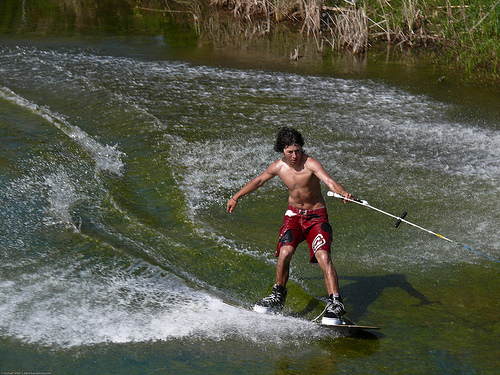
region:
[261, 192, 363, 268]
Man wearing red shorts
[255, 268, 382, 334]
man on a water board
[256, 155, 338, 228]
man without a shirt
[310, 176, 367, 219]
man holding a line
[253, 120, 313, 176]
man with black hair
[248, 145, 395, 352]
man water skiing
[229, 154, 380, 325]
man skiing through water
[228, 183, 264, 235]
man with band on wrist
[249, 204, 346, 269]
man wearing red and black shorts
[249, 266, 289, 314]
man with black boots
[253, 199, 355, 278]
the short is red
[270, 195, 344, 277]
the short is red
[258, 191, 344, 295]
the short is red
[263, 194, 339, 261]
the short is red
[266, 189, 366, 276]
the short is red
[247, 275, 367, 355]
the shoes are black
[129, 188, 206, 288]
the water is murky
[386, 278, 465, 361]
the water is murky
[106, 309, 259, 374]
the water is murky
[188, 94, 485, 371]
Person on the water.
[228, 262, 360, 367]
Man water skiing.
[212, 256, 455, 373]
Tennis shoes on the water ski.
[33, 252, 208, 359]
Foam on the water.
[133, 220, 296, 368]
Waves in the water.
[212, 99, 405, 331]
Boy in red shorts.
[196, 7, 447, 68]
Grass on the water.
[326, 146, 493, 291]
Rope attached to the boat.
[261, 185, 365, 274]
White black and red shorts.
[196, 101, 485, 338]
Man with brunette hair.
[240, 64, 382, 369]
boy on a wakeboard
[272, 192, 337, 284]
boy wearing red swim trunks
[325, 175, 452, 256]
waterski rope in hand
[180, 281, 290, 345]
waves on the lake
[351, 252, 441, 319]
shadow on the water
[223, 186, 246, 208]
bracelet on wrist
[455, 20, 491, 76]
grass on the shoreline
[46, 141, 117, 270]
waves on the lake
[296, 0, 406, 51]
sticks on the shoreline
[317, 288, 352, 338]
foot in wakeboard binding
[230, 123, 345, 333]
young man water skiing on river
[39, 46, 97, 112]
green and white river water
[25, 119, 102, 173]
green and white river water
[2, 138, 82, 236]
green and white river water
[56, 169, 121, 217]
green and white river water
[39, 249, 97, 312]
green and white river water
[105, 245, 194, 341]
green and white river water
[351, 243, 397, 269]
green and white river water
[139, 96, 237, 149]
green and white river water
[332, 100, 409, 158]
green and white river water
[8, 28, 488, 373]
a body of water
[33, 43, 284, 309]
wave in the water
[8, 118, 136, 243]
splash of the water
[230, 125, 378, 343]
man on a board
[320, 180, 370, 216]
man holding on to a handle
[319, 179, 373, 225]
the handle is white